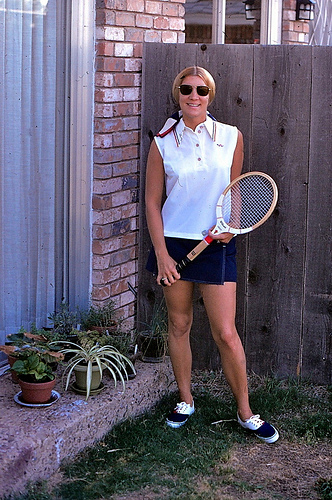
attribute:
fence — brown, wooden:
[142, 38, 330, 324]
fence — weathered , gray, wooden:
[229, 29, 325, 158]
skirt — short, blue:
[138, 226, 250, 287]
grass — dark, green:
[65, 390, 330, 498]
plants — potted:
[7, 303, 165, 411]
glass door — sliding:
[3, 0, 84, 365]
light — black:
[293, 0, 315, 23]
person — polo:
[144, 64, 280, 444]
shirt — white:
[154, 110, 237, 240]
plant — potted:
[14, 352, 64, 379]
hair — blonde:
[164, 63, 219, 102]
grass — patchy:
[82, 419, 234, 483]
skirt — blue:
[143, 226, 242, 284]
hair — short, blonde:
[147, 62, 216, 97]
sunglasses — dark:
[174, 83, 211, 96]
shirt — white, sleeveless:
[162, 119, 231, 235]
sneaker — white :
[168, 403, 281, 446]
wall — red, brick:
[90, 17, 143, 328]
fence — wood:
[136, 40, 331, 383]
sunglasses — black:
[177, 83, 212, 96]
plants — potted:
[12, 319, 107, 393]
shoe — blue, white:
[234, 409, 278, 444]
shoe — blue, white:
[164, 399, 195, 428]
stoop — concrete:
[0, 346, 178, 498]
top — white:
[152, 115, 238, 243]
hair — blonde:
[167, 64, 215, 111]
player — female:
[145, 64, 280, 444]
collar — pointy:
[171, 115, 218, 146]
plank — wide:
[131, 40, 198, 361]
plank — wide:
[195, 41, 252, 370]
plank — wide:
[244, 40, 312, 393]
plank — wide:
[299, 44, 331, 385]